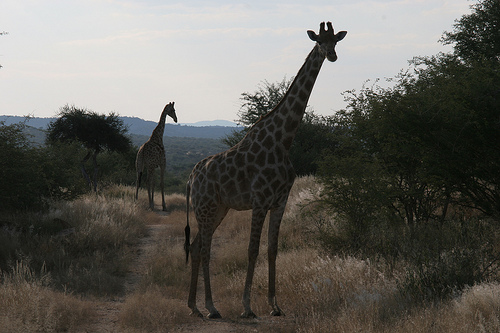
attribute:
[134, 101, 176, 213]
giraffe — looking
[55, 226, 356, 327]
grass — brown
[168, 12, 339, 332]
giraffe — tall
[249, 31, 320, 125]
mane — brown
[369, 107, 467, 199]
trees — leafy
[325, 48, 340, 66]
nose — brown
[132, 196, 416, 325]
grass — dead